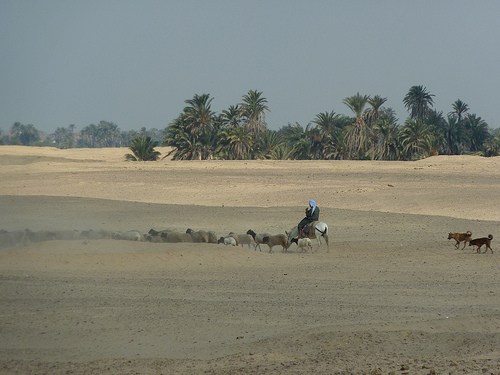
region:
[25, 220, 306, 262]
Line of sheep walking in the dirt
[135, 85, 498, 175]
Group of palm trees in the background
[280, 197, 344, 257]
Man riding a donkey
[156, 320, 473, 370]
Stones on top of the dust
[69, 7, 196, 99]
Sky is blue with no clouds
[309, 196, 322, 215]
Man wearing blue cloth on head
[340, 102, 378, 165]
Dried leaves on the palm tree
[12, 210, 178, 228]
Dust surrounding the sheep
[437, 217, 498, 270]
Two dogs following the pack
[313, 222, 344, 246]
Donkey flicking its tail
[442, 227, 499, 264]
two brown herding dogs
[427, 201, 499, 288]
two brown herding dogs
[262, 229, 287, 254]
a black and white sheep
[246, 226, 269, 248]
a black and white sheep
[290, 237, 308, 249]
a black and white sheep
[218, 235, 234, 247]
a black and white sheep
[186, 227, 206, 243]
a black and white sheep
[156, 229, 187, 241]
a black and white sheep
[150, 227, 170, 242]
a black and white sheep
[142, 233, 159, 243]
a black and white sheep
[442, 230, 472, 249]
a brown walking dog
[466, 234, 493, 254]
a brown walking dog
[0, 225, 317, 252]
a herd of sheep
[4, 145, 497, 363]
sand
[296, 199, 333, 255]
a person riding a horse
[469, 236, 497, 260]
a dark brown dog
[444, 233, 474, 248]
a tan dog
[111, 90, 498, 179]
a line of tropical palm trees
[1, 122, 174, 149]
a distant tropical treeline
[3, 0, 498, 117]
a gray sky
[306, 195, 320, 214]
a blue head cover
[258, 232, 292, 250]
a tan sheep with a black head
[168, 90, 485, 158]
Cluster of palm trees.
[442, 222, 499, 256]
Two dogs walking.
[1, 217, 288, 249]
A herd of sheep.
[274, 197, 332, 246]
Man riding a white donkey.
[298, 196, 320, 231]
Man wearing a pale blue headscarf.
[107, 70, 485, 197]
Oasis in a desert.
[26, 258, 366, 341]
Bare desert landscape.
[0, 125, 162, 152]
Treeline on a desert horizon.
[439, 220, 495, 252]
Two brown sheepdogs.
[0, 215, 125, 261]
Sheep obscured by a dust cloud.